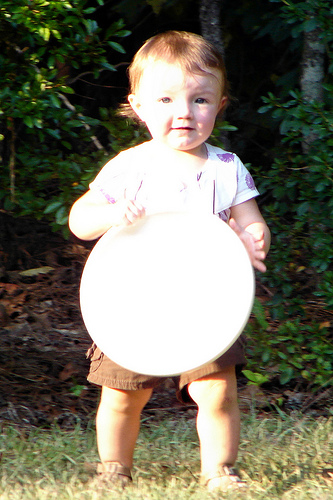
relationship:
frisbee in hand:
[96, 200, 285, 398] [107, 193, 167, 240]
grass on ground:
[3, 408, 332, 499] [1, 265, 332, 497]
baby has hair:
[65, 30, 273, 483] [120, 20, 240, 82]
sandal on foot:
[67, 445, 141, 492] [195, 455, 254, 493]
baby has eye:
[65, 30, 273, 483] [156, 93, 171, 104]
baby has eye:
[65, 30, 273, 483] [188, 95, 208, 106]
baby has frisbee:
[65, 30, 273, 483] [78, 210, 254, 376]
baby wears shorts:
[65, 30, 273, 483] [53, 337, 257, 406]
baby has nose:
[65, 30, 273, 483] [176, 98, 192, 120]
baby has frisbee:
[65, 30, 273, 483] [76, 180, 258, 387]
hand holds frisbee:
[111, 197, 146, 228] [78, 210, 254, 376]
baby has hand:
[65, 30, 273, 483] [111, 197, 146, 228]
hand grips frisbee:
[227, 216, 270, 274] [78, 210, 254, 376]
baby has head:
[65, 30, 273, 483] [126, 26, 228, 153]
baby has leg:
[65, 30, 273, 483] [187, 362, 248, 492]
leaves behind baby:
[238, 298, 332, 394] [65, 30, 273, 483]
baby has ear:
[65, 30, 273, 483] [125, 91, 144, 124]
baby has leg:
[56, 30, 253, 485] [92, 379, 156, 478]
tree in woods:
[298, 0, 328, 182] [0, 0, 332, 282]